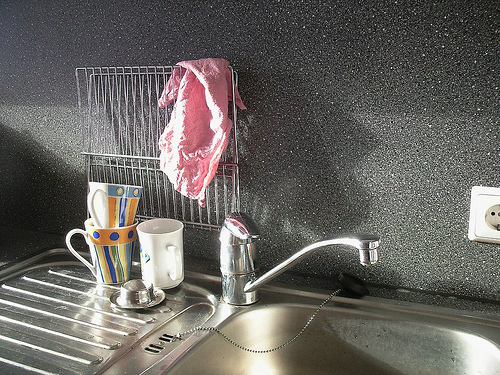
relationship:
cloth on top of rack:
[158, 58, 246, 206] [77, 67, 238, 231]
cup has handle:
[66, 218, 138, 283] [66, 229, 96, 278]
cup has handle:
[88, 181, 142, 226] [88, 189, 107, 227]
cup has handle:
[137, 217, 184, 288] [167, 246, 181, 281]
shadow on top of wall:
[98, 63, 381, 237] [0, 0, 499, 303]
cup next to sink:
[66, 218, 138, 283] [148, 303, 499, 374]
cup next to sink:
[88, 181, 142, 226] [148, 303, 499, 374]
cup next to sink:
[137, 217, 184, 288] [148, 303, 499, 374]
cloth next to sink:
[158, 58, 246, 206] [148, 303, 499, 374]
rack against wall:
[77, 67, 238, 231] [0, 0, 499, 303]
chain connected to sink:
[171, 284, 344, 353] [148, 303, 499, 374]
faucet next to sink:
[220, 213, 380, 304] [148, 303, 499, 374]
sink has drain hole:
[148, 303, 499, 374] [144, 346, 158, 353]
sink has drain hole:
[148, 303, 499, 374] [150, 343, 163, 349]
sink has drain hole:
[148, 303, 499, 374] [161, 335, 170, 342]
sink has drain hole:
[148, 303, 499, 374] [165, 334, 175, 338]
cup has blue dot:
[66, 218, 138, 283] [110, 232, 119, 240]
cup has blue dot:
[66, 218, 138, 283] [93, 233, 99, 239]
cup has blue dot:
[66, 218, 138, 283] [129, 230, 133, 238]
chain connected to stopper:
[171, 284, 344, 353] [338, 274, 367, 294]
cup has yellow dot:
[88, 181, 142, 226] [116, 187, 124, 194]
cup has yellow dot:
[88, 181, 142, 226] [133, 191, 139, 195]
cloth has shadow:
[158, 58, 246, 206] [244, 75, 378, 237]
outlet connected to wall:
[469, 185, 499, 243] [0, 0, 499, 303]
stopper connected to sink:
[338, 274, 367, 294] [148, 303, 499, 374]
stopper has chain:
[338, 274, 367, 294] [171, 284, 344, 353]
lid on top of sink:
[110, 280, 164, 308] [0, 263, 185, 374]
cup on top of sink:
[137, 217, 184, 288] [0, 263, 185, 374]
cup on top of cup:
[88, 181, 142, 226] [66, 218, 138, 283]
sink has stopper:
[148, 303, 499, 374] [338, 274, 367, 294]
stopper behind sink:
[338, 274, 367, 294] [148, 303, 499, 374]